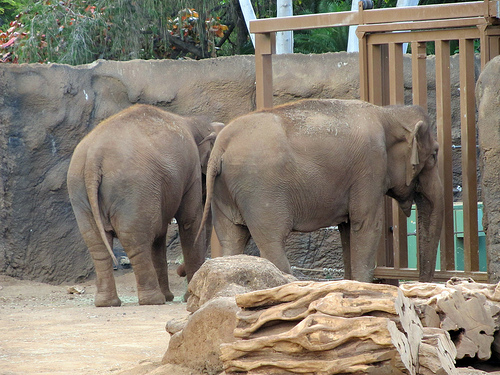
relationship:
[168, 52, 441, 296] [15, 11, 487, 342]
elephant in cage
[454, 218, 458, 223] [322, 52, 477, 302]
water outside fence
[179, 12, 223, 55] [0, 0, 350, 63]
grass and grass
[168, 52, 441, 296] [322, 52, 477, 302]
elephant in fence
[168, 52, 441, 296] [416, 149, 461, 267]
elephant has trunk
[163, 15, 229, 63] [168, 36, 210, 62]
tree has trunk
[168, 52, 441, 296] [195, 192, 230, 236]
elephant has tail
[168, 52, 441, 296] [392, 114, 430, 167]
elephant has ear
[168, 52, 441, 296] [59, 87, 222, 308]
elephant next elephant